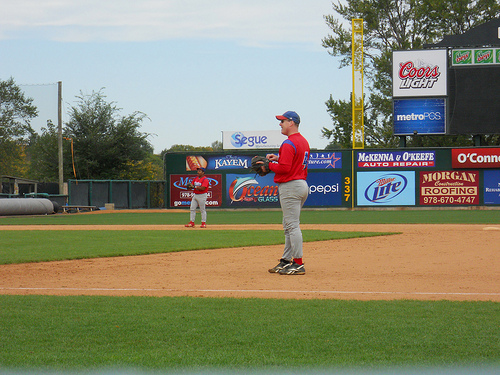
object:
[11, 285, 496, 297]
line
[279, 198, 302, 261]
leg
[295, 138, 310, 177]
back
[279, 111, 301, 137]
head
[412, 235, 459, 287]
soil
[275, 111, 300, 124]
cap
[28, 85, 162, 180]
plants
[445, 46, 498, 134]
scoreboard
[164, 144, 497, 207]
fence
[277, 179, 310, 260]
gray pants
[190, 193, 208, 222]
gray pants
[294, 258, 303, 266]
socks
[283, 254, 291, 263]
socks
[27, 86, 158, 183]
trees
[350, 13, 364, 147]
pole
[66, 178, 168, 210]
fence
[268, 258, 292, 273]
shoe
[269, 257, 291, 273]
foot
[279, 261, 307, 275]
shoe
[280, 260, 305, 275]
foot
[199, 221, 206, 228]
shoes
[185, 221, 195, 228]
shoe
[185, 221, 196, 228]
foot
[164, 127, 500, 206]
billboards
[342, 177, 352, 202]
yellow paint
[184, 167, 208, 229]
man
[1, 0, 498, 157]
sky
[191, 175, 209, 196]
shirt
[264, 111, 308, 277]
fielder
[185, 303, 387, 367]
grass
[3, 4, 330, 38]
clouds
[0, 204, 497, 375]
field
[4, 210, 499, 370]
floor